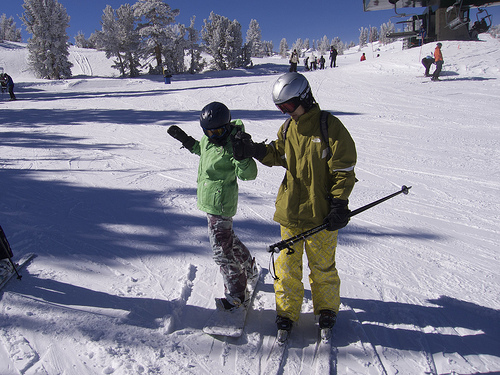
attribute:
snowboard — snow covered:
[195, 295, 260, 345]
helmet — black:
[198, 99, 231, 131]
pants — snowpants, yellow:
[271, 220, 341, 318]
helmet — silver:
[270, 70, 312, 103]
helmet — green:
[195, 98, 236, 140]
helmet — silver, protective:
[266, 74, 309, 101]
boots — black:
[277, 305, 344, 330]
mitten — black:
[161, 112, 188, 142]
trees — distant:
[216, 25, 424, 51]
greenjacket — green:
[179, 124, 258, 214]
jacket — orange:
[433, 46, 447, 63]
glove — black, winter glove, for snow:
[327, 196, 350, 230]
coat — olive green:
[247, 113, 357, 228]